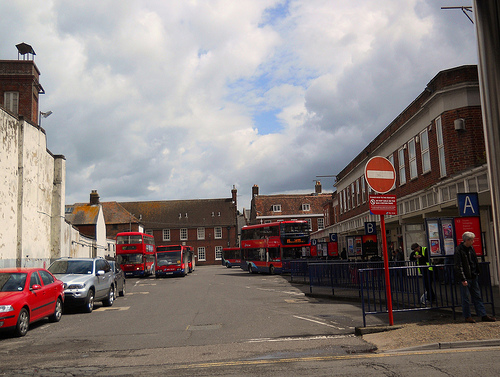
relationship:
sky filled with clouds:
[2, 3, 479, 212] [58, 6, 205, 142]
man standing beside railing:
[450, 228, 496, 323] [355, 258, 495, 326]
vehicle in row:
[109, 232, 156, 277] [0, 230, 194, 334]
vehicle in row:
[46, 256, 126, 313] [0, 230, 194, 334]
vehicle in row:
[99, 256, 124, 291] [0, 230, 194, 334]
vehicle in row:
[154, 244, 195, 273] [0, 230, 194, 334]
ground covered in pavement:
[2, 259, 498, 375] [1, 261, 498, 375]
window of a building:
[401, 132, 423, 182] [312, 65, 489, 267]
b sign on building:
[364, 219, 378, 231] [308, 67, 498, 256]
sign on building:
[344, 144, 411, 216] [249, 63, 497, 323]